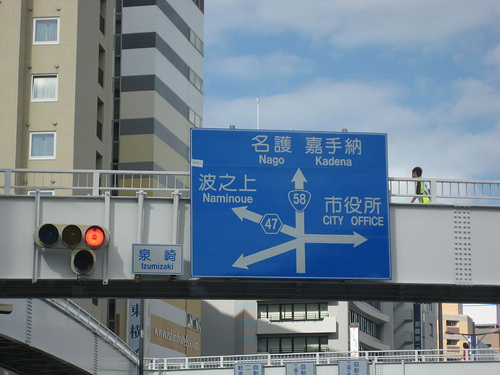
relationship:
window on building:
[32, 17, 60, 47] [0, 1, 207, 357]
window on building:
[32, 73, 59, 101] [0, 1, 207, 357]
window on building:
[29, 130, 57, 158] [0, 1, 207, 357]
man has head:
[407, 167, 433, 205] [410, 165, 424, 177]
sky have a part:
[203, 2, 499, 205] [381, 86, 472, 123]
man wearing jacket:
[407, 167, 433, 205] [417, 183, 432, 205]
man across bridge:
[407, 167, 433, 205] [3, 166, 495, 370]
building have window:
[0, 1, 207, 357] [32, 17, 60, 47]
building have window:
[0, 1, 207, 357] [32, 73, 59, 101]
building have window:
[0, 1, 207, 357] [29, 130, 57, 158]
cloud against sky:
[197, 0, 499, 205] [203, 2, 499, 205]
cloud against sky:
[207, 47, 312, 84] [203, 2, 499, 205]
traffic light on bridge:
[35, 224, 108, 274] [3, 166, 495, 370]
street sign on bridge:
[192, 128, 391, 281] [3, 166, 495, 370]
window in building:
[32, 17, 60, 47] [0, 1, 207, 357]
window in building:
[32, 73, 59, 101] [0, 1, 207, 357]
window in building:
[29, 130, 57, 158] [0, 1, 207, 357]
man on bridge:
[407, 167, 433, 205] [3, 166, 495, 370]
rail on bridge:
[1, 165, 499, 206] [3, 166, 495, 370]